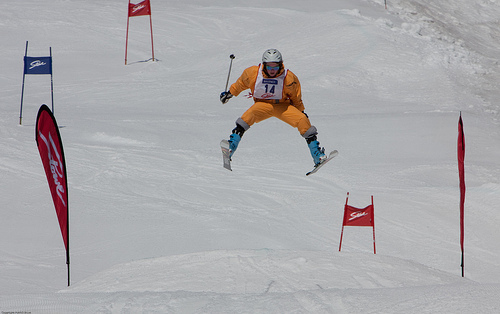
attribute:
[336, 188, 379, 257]
mark — short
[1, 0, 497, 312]
snow — white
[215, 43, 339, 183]
skier — mid air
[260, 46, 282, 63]
helmet — white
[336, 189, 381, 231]
flag — red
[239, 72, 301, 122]
ski suit — orange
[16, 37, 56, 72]
banner — blue, white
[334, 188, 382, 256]
banner — red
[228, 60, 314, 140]
ski suit — orange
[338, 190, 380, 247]
flag — red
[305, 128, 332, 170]
boots — black, blue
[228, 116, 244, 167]
boots — blue, black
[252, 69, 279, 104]
bib — white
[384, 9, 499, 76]
snow — piled, on side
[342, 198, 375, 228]
flag — red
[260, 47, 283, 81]
helmet — grey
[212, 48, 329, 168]
snowboarder — airborne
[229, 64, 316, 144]
ski suit — yellow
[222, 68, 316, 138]
snowsuit — yellow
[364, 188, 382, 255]
stick — red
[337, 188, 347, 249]
stick — red